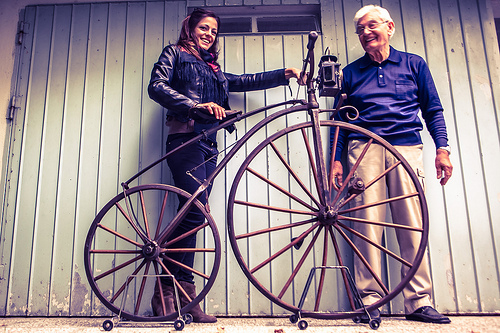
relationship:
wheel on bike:
[243, 135, 409, 304] [135, 62, 417, 296]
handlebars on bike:
[294, 33, 310, 89] [135, 62, 417, 296]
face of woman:
[192, 22, 226, 51] [141, 17, 236, 289]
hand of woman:
[189, 95, 245, 128] [141, 17, 236, 289]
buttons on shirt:
[376, 66, 385, 90] [369, 63, 433, 127]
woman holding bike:
[141, 17, 236, 289] [135, 62, 417, 296]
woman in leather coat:
[141, 17, 236, 289] [162, 46, 235, 127]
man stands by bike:
[335, 11, 444, 279] [135, 62, 417, 296]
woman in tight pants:
[141, 17, 236, 289] [162, 133, 199, 277]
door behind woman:
[107, 40, 129, 78] [141, 17, 236, 289]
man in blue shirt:
[335, 11, 444, 279] [365, 110, 375, 116]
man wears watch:
[335, 11, 444, 279] [433, 142, 495, 162]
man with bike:
[335, 11, 444, 279] [135, 62, 417, 296]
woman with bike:
[141, 17, 236, 289] [135, 62, 417, 296]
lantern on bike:
[314, 51, 350, 156] [135, 62, 417, 296]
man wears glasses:
[335, 11, 444, 279] [345, 15, 396, 37]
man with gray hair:
[335, 11, 444, 279] [347, 9, 396, 18]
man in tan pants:
[335, 11, 444, 279] [351, 143, 437, 297]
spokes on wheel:
[358, 171, 411, 236] [243, 135, 409, 304]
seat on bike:
[185, 101, 236, 122] [135, 62, 417, 296]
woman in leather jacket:
[141, 17, 236, 289] [166, 48, 197, 83]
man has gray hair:
[335, 11, 444, 279] [352, 4, 396, 40]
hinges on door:
[9, 28, 48, 50] [107, 40, 129, 78]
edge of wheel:
[334, 117, 347, 127] [243, 135, 409, 304]